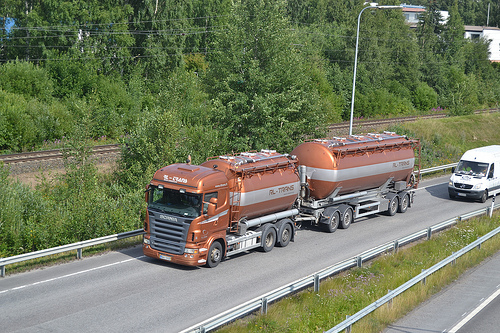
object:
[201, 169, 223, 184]
copper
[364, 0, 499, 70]
house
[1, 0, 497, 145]
trees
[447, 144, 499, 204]
van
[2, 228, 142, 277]
guardrail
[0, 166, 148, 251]
side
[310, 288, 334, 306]
flowers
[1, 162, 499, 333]
freeway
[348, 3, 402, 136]
lamp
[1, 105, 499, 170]
tracks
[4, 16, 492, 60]
lines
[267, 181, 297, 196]
writing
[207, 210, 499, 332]
grass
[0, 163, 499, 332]
road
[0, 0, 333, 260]
trees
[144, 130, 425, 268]
truck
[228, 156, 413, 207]
stripe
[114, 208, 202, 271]
shadow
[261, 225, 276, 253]
wheel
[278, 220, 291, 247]
wheel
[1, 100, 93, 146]
shrubs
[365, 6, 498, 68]
building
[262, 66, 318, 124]
leaves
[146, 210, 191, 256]
grill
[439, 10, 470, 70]
tree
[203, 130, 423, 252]
two rigs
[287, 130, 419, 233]
rig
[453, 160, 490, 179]
windshield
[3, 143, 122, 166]
train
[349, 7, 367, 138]
pole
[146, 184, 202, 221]
windshield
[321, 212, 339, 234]
wheels